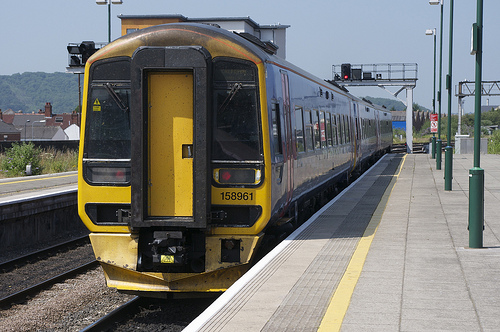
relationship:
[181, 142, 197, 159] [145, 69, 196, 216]
handle on door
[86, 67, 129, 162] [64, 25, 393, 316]
window on train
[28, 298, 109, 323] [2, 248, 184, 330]
gravel on tracks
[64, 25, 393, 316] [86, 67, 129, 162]
train has window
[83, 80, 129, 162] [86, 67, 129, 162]
window left window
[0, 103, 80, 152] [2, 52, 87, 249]
buildings to left of train